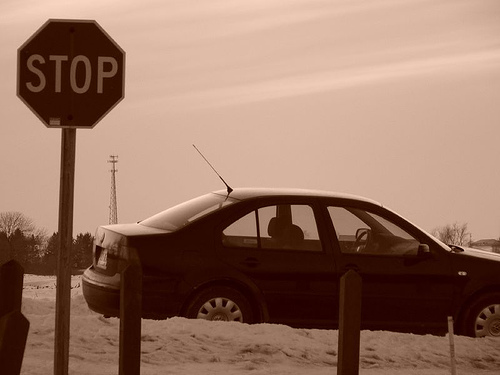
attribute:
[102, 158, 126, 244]
tower — power line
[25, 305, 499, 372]
snow — deep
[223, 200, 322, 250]
window — clear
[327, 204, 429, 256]
window — clear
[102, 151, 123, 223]
tower — tall, metal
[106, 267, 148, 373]
posts — wooden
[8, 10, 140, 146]
sign — red, white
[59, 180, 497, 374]
car — small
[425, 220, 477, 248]
tree — small, bare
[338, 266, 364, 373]
pole — wood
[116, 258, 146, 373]
pole — wood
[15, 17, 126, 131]
stop sign — red, white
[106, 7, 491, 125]
clouds — streaky